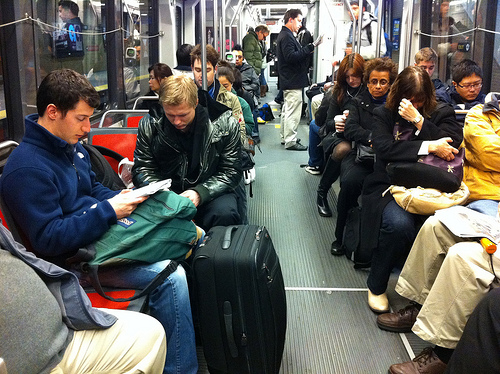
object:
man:
[1, 68, 200, 373]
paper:
[90, 178, 174, 208]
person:
[365, 64, 463, 314]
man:
[275, 9, 314, 153]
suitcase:
[188, 224, 287, 373]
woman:
[141, 64, 173, 109]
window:
[111, 0, 155, 107]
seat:
[87, 130, 137, 176]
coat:
[1, 111, 119, 256]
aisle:
[247, 85, 410, 373]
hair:
[334, 53, 366, 104]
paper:
[310, 34, 322, 47]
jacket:
[131, 93, 241, 205]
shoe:
[376, 300, 420, 334]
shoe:
[387, 348, 447, 374]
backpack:
[77, 189, 197, 301]